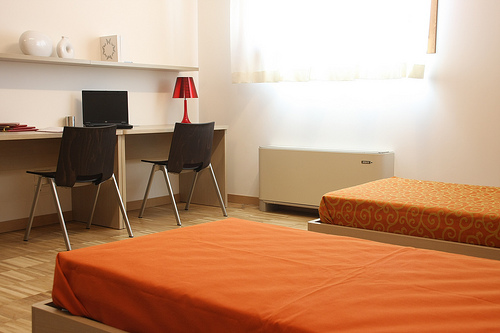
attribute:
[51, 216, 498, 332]
fabric — orange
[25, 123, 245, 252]
chairs — black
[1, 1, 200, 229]
wall — white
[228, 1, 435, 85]
curtain — white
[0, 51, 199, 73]
shelf — long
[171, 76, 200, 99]
lampshade — red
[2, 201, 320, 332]
floor — wooden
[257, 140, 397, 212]
unit — white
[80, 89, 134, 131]
laptop — black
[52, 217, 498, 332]
sheet — orange, red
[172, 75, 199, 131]
lamp — red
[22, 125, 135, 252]
chair — black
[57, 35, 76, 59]
vase — white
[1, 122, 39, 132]
folder — red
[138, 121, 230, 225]
chair — black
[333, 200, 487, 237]
pattern — yellow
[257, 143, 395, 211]
radiator — white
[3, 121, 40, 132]
plates — red